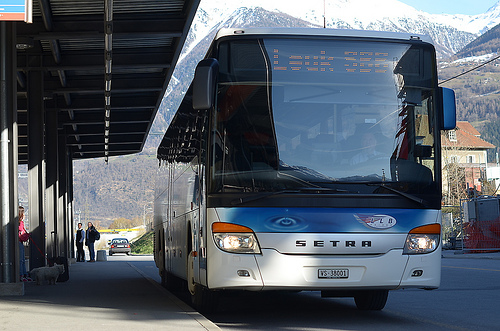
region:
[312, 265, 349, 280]
license plate on bus.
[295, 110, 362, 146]
windshield of the bus.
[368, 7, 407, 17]
snow on the mountain.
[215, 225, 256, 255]
headlight on front of bus.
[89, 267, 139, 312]
shadow on the sidewalk.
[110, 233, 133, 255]
vehicle driving behind bus.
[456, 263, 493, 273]
yellow paint on road.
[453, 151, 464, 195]
bare limbs on tree.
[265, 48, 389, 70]
electronic sign on bus.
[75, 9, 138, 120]
roof over bus platform.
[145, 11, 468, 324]
a bus on the road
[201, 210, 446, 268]
headlights in front a bus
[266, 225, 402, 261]
word setra in front a bus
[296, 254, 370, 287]
white tag on bumper of bus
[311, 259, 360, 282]
tag has black letters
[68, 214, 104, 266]
two people in front a building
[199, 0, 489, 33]
mountain with white snow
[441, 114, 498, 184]
a building with red roof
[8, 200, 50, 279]
person wearing red shirt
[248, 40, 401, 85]
orange letters on top of bus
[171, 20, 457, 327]
the bus on the street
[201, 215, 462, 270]
the headlights of thebus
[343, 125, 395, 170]
the bus driver is driving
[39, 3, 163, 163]
the awning over the sidewalk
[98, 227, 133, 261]
the car on the street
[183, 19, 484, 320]
the bus is parked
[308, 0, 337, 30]
the antenna on the bus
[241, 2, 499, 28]
snow on the mountain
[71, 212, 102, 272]
people on the sidewalk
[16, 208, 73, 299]
the woman with her dog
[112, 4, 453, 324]
a bus parked on the road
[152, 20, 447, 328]
a bus on the street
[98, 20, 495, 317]
a bus parked on the street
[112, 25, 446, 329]
a bus parked on the side of the street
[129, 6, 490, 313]
a bus parked on the side of the road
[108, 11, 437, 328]
a setra bus on the road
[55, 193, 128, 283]
people standing on a sidewalk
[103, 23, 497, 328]
a bus with headlights on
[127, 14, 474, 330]
a passenger bus on the road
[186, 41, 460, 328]
The bus is parked at bus terminal.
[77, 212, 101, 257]
People standing on the sidewalk.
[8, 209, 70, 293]
A person walking a dog.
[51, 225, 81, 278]
A suitcase on the ground.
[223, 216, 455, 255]
The headlight of the bus is on.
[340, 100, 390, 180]
The driver is sitting on the bus.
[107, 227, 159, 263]
A car riding down the street.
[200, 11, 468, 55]
Snow on top of the mountains.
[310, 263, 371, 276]
A tag plate on the front of the bus.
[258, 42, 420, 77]
The sign on the bus is in red letters.